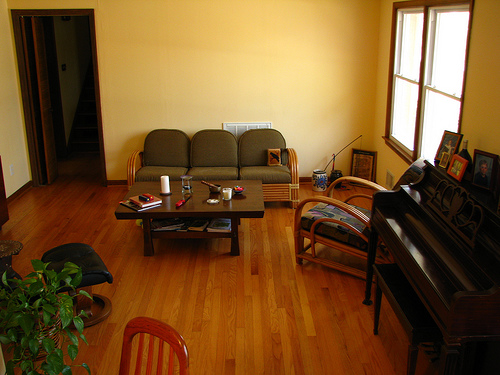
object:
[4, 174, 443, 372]
floor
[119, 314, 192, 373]
chair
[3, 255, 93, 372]
plant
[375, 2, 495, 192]
wall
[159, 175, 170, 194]
candle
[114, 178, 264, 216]
table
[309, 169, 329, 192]
vase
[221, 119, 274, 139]
vent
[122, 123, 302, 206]
sofa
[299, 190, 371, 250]
cushion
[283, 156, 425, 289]
chair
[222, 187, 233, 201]
cup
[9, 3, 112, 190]
door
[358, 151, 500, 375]
piano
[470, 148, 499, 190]
picture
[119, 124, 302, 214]
couch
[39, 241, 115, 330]
seat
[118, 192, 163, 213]
books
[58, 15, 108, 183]
stairs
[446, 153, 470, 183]
photo frame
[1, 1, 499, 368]
room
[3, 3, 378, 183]
wall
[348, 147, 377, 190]
picture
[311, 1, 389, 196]
corner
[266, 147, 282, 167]
pillow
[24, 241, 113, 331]
foot stool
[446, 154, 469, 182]
picture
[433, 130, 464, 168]
picture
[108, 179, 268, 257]
coffee table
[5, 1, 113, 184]
door frame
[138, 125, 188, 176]
cushions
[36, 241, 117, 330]
ottoman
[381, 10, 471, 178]
window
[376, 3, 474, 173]
frame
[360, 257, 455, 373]
piano bench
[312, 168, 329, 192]
jar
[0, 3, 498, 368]
living room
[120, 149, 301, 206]
trim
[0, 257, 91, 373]
vine plant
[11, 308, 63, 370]
basket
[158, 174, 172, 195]
objects